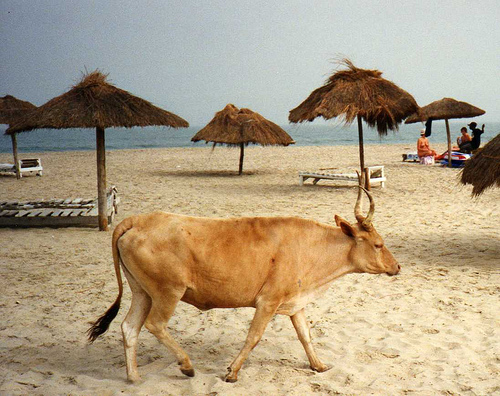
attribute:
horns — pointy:
[349, 174, 392, 232]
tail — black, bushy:
[64, 262, 149, 345]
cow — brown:
[99, 212, 395, 389]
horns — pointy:
[339, 164, 412, 237]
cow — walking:
[86, 219, 463, 373]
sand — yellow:
[180, 159, 340, 226]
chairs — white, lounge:
[13, 177, 126, 235]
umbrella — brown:
[34, 73, 192, 169]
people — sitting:
[396, 123, 476, 176]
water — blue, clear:
[37, 118, 209, 174]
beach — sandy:
[67, 140, 340, 231]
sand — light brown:
[286, 300, 415, 375]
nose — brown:
[347, 245, 455, 314]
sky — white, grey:
[119, 27, 339, 147]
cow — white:
[76, 189, 417, 392]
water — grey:
[164, 75, 305, 190]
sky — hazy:
[175, 42, 258, 118]